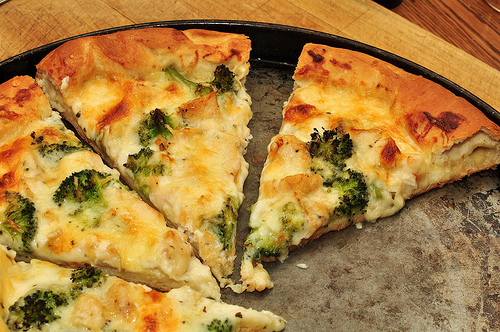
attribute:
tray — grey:
[0, 20, 498, 331]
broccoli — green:
[327, 169, 370, 216]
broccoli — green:
[7, 288, 67, 331]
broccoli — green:
[55, 169, 114, 204]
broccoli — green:
[136, 109, 180, 145]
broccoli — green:
[307, 128, 354, 166]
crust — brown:
[59, 30, 233, 66]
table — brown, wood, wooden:
[1, 2, 499, 332]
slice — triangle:
[242, 42, 500, 283]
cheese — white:
[173, 135, 241, 188]